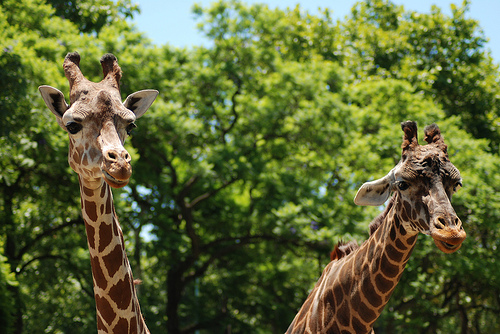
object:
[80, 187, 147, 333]
neck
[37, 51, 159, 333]
giraffe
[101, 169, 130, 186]
mouth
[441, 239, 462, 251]
mouth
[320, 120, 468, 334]
giraffe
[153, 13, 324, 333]
tree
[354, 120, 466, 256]
head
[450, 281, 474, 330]
tree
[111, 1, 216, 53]
sky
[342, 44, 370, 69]
leaves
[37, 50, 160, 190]
head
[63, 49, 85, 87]
horn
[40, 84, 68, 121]
ear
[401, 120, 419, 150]
horn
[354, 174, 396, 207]
ear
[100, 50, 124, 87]
horn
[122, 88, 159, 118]
ear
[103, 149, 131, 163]
nose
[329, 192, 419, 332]
neck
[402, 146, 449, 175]
forehead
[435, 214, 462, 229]
nose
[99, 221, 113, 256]
spot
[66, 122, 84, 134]
eye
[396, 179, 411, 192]
eye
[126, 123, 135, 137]
eye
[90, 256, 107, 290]
spot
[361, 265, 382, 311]
spot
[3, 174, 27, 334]
tree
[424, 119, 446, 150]
horn